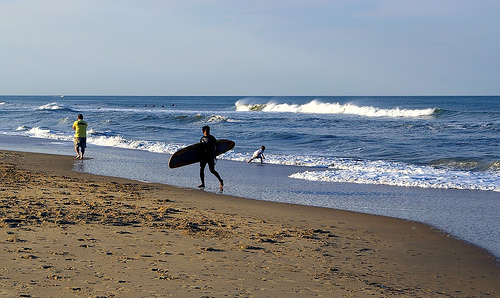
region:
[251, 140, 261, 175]
the child is on the beach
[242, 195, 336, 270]
foot is on the sand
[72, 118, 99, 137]
the shirt is yellow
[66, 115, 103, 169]
the man is wearing shorts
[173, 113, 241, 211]
the guy is holding a surfboard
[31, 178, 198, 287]
the sand is brown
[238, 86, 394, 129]
waves are in the sea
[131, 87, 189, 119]
birds are in the sea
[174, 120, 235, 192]
the guy is bare foot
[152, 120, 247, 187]
the man is in a swimsuit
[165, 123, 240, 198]
A man carrying a surfboard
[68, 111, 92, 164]
A man walking on the beach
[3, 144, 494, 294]
The sand of a beach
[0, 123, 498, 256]
Waves washing in on a beach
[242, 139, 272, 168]
A child playing at the beach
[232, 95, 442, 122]
The foam of a wave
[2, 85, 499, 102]
The horizon of sea and sky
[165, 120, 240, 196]
A surfer at the beach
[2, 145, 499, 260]
Water coming onto sand on a beach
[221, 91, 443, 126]
A rolling wave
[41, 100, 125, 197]
man walking at the beach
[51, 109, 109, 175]
man walking at the beach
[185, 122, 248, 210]
surfer carrying a surfboard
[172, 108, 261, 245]
surfer carrying a surfboard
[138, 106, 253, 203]
surfer carrying a surfboard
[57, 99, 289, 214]
three people in the beach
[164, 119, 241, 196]
person holding a surfboard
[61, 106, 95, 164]
man wears a yellow shirt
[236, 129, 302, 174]
a kid near a wave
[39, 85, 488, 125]
a wave forming in the ocean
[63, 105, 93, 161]
man is barefeet on sand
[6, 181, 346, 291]
footprints over the sand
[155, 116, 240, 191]
person holding a surfboard under his arm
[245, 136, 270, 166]
kid is bend forward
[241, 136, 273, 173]
kid wears a white short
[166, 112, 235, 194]
man with surfboard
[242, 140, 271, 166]
child playing at water's edge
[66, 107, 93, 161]
man in yellow shirt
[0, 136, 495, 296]
wet sand on beach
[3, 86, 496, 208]
waves in ocean water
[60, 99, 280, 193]
people enjoying the beach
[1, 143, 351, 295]
wet brown sand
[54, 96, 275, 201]
people walking in water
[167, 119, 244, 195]
man carrying black surfboard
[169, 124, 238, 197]
man dressed in black wetsuit